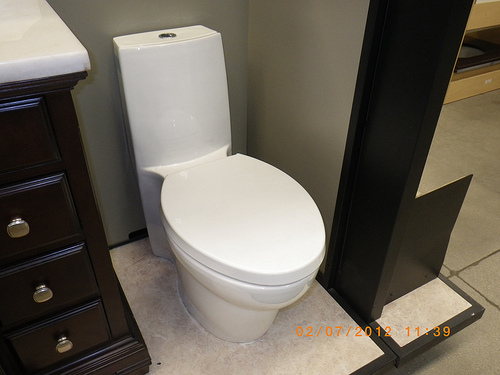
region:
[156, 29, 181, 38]
flush valve for toilet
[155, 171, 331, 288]
Part of closed toilet lid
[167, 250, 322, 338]
Part of white toilet base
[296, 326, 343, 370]
Part of white bathroom floor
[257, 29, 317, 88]
Part of bathroom wall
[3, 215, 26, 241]
Handle for sink drawer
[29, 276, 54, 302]
Handle for sink drawer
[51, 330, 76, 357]
Handle for sink drawer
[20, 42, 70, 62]
Part of white bathroom sink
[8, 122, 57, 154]
Part of brown bathroom drawer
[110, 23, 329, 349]
toilet against a gray wall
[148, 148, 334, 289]
toilet seat on toilet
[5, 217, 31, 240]
hardware pull on drawer of sink cabinet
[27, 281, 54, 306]
hardware pull on drawer of sink cabinet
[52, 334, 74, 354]
hardware pull on drawer of sink cabinet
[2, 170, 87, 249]
first drawer of the sink cabinet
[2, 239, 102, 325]
second drawer of the sink cabinet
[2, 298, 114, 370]
Third drawer of the sink cabinet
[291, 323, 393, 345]
date the picture was made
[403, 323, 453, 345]
time the picture was taken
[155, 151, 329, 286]
the lid of a toilet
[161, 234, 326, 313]
the bowl of a toilet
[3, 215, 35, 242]
a metal drawer knob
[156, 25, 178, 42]
a button on the toilet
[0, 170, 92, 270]
a black wooden drawer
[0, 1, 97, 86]
a white counter top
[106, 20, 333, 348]
a white porcelain toilet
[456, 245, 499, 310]
a gray tile on the floor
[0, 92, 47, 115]
light shining on the drawer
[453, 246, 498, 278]
a crack in the floor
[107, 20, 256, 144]
White toilet tank resevoir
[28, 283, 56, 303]
Handle on sink drawer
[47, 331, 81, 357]
Handle on sink drawer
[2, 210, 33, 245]
Handle on sink drawer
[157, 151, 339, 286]
Lid on closed toilet seat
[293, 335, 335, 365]
Part of bathroom tile floor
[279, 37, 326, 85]
Part of bathroom wall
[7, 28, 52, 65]
Part of top of bathroom sink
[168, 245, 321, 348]
Part of white toilet bowl base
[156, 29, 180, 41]
Flush lever for toilet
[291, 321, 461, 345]
orange date and time stamp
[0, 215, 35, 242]
a silver drawer knob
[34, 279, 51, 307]
a silver drawer knob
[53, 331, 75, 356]
a silver drawer knob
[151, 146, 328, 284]
a white toilet lid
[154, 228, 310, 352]
a white toilet bowl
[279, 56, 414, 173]
grey and black bathroom partition wall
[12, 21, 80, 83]
white marble counter top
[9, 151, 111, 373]
a set of dark wood drawers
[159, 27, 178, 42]
silver flush button on a toilet